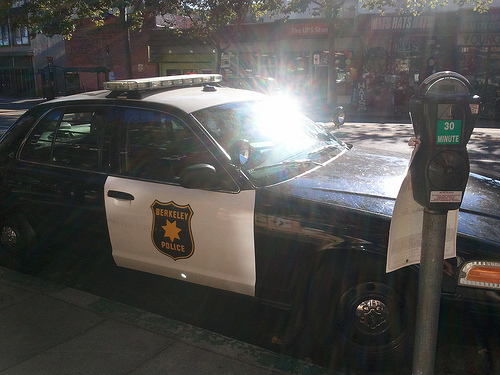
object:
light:
[242, 94, 318, 159]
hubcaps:
[352, 297, 392, 333]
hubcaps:
[0, 225, 18, 253]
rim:
[0, 213, 37, 263]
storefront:
[441, 13, 499, 103]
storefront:
[356, 11, 434, 121]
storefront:
[267, 9, 331, 113]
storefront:
[214, 23, 281, 89]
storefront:
[151, 21, 232, 80]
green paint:
[87, 295, 329, 374]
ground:
[306, 114, 500, 182]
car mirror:
[327, 104, 346, 127]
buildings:
[63, 0, 500, 114]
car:
[0, 72, 498, 359]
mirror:
[177, 163, 220, 188]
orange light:
[467, 264, 497, 285]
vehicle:
[0, 74, 498, 357]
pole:
[410, 212, 449, 374]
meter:
[409, 72, 481, 374]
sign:
[356, 81, 368, 117]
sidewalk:
[307, 100, 499, 127]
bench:
[65, 84, 100, 93]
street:
[0, 104, 500, 179]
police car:
[0, 73, 499, 373]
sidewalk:
[1, 255, 334, 373]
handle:
[107, 189, 137, 199]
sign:
[383, 142, 464, 272]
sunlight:
[244, 85, 321, 151]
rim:
[349, 295, 396, 342]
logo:
[149, 194, 197, 263]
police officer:
[211, 111, 268, 165]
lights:
[103, 68, 225, 93]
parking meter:
[407, 69, 481, 374]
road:
[0, 87, 499, 171]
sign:
[433, 119, 462, 146]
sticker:
[149, 197, 197, 258]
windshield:
[203, 92, 350, 189]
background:
[1, 0, 499, 111]